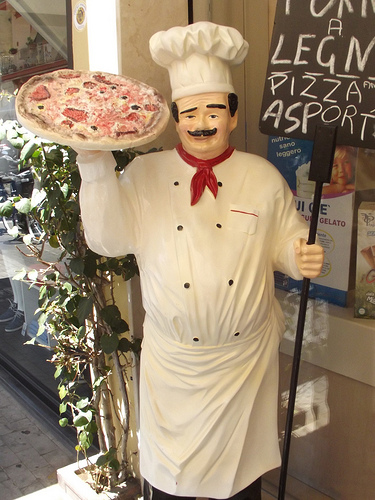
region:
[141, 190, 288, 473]
the apron is white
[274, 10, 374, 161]
the body is balck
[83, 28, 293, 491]
the chef is holding a pizza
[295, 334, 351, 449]
refflection is on the wall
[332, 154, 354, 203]
picture of a baby is on the paper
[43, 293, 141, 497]
plant is growing against the wall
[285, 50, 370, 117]
the writing is white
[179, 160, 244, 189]
the scarf is red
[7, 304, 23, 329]
the shoes are grey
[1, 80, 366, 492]
it is daytime in the photo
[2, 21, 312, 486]
a life sized statue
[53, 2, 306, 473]
the statue is a chef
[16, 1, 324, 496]
the statue is holding a pizza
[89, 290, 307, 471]
the statue is wearing an apron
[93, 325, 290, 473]
the apron is white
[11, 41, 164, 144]
the pizza has olives on it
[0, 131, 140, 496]
there is a potted tree by the statue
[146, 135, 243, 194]
the man is wearing a red scarf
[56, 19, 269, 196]
the statue is a male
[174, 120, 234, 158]
the statue has a mustache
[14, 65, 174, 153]
round pizza recreation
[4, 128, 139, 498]
potted plant behind statue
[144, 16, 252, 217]
cook wears mustache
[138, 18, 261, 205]
cook wears tall chef hat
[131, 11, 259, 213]
cook wears red bandana around neck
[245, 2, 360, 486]
statue holding black board sign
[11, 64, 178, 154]
black olives on pizza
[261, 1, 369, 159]
sign with italian language on it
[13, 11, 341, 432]
statue holding pizza in right hand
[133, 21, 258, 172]
statue head frowning eyebrow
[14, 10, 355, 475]
Statue of a chef holding a pizza.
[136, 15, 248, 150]
A white chef's hat on statue.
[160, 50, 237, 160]
Mustache on a statue.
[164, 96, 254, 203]
Red kerchief around neck of statue.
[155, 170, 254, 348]
Black buttons on statute's shirt.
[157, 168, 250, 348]
Eight buttons on statute's shirt.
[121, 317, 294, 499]
White apron on statute.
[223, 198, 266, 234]
Red stripe on pocket of statue's shirt.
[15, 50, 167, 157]
Pizza is part of a statue.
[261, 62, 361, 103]
The word PIZZA on a chalkboard.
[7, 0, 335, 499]
beware of plastic pizzamen bearing plastic pizzas. 'plastic' might actually be 'plaster'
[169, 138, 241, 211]
unliving pizza chef wears unfabric red neck scarf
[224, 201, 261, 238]
carved pocket has painted red stripe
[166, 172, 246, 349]
eight buttons across the onset of a pizza-belly, none of which are really there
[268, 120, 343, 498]
our not-even-robotic pizzaman holds black stick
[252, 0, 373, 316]
atop black stick is a come on for pizza, etc & ect. everything in this scene is written in italian, scene likely takes place there.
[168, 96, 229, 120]
our pizzaman has one very thick eyebrow, & one thin eyebrow. they dont join at an arc in the middle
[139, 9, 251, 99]
pizzaman wears chef's hat w/ stereotypical apex puff, but it, too, is not fabric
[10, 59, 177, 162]
pizza mannequin holds a not particularly appetizing fake pizza w/ toppings that cannot be found in nature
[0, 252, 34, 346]
a real human's white socks+black shoes w/ white laces are reflected in the next window